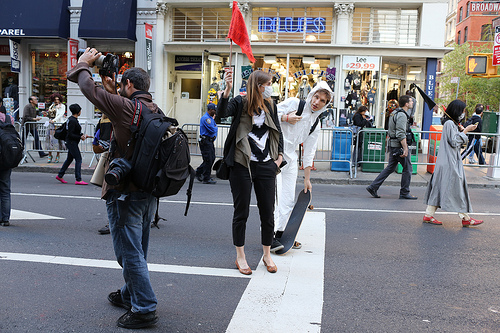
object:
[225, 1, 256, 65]
flag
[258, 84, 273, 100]
mask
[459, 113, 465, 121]
mask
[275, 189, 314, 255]
skateboard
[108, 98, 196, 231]
backpack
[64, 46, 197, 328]
man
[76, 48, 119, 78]
camera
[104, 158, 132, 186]
camera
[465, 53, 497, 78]
signal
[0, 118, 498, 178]
fence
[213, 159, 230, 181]
pocketbook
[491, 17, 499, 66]
signs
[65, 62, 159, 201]
shirt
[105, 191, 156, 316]
jeans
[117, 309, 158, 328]
shoes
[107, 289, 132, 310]
man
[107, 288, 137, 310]
shoes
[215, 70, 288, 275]
lady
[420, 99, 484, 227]
people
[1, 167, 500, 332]
street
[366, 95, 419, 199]
people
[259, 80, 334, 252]
people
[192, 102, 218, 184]
people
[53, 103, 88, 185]
people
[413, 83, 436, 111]
flag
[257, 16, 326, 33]
sign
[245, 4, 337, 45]
window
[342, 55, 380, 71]
sign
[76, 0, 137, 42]
awning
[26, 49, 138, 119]
window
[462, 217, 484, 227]
shoes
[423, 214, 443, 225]
shoes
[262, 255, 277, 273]
shoes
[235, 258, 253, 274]
shoes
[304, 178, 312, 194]
hand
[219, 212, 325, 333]
line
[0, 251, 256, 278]
line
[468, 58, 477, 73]
hand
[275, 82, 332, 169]
shirt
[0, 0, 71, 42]
awning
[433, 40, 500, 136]
tree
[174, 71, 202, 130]
door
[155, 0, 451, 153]
building